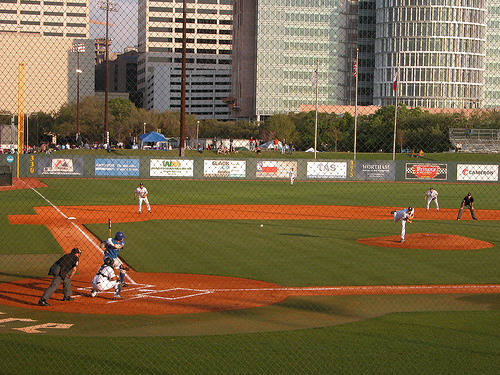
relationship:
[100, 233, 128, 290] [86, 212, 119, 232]
man holding bat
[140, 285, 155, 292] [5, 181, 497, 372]
home plate on field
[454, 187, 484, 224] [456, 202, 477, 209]
man bent down with hands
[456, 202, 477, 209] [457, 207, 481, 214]
hands on knees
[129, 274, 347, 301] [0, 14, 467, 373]
lines on field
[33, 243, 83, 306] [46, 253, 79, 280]
man wearing vest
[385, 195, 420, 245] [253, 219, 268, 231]
pitcher threw ball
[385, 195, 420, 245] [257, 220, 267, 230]
pitcher throwing pitch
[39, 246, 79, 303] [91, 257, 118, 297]
unmpire crouching behind catcher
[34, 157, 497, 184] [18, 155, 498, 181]
signs on wall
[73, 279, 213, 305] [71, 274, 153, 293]
white lines around box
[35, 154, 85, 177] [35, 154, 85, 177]
sign on sign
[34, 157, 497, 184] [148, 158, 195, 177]
signs on banner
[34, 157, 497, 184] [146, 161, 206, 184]
signs on banner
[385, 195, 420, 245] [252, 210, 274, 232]
pitcher throwing ball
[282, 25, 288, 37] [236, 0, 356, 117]
window of building